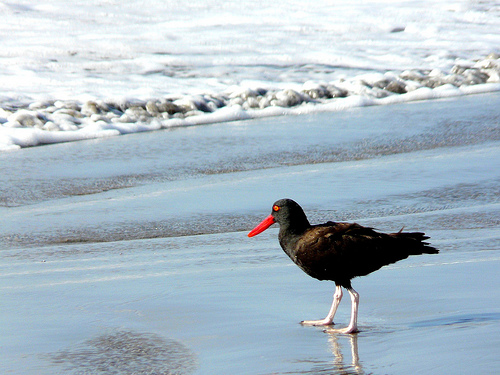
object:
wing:
[296, 220, 439, 281]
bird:
[248, 198, 439, 335]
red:
[248, 214, 276, 237]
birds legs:
[300, 280, 343, 326]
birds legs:
[323, 285, 360, 334]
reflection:
[300, 325, 361, 373]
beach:
[0, 90, 499, 374]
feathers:
[312, 235, 374, 269]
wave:
[4, 3, 496, 155]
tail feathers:
[387, 227, 440, 260]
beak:
[247, 214, 276, 238]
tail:
[398, 225, 443, 262]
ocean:
[0, 0, 500, 91]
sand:
[231, 287, 306, 349]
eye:
[271, 205, 279, 211]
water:
[1, 0, 499, 152]